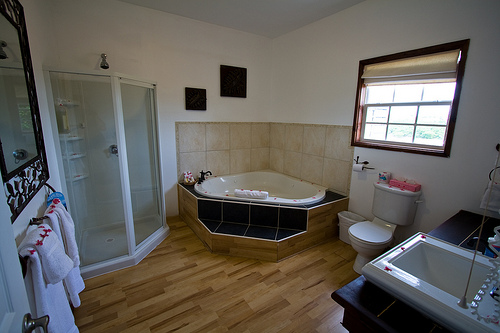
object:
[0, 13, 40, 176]
mirror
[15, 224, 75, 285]
towel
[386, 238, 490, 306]
white sink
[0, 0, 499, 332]
bathroom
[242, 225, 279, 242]
tile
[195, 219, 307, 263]
stairs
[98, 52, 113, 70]
shower head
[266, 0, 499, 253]
wall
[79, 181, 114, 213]
glass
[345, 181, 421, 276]
toilet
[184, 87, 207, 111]
pictures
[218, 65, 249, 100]
pictures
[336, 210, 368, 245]
waste bucket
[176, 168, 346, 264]
bathtub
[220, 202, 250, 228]
tile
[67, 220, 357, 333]
floor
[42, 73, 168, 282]
shower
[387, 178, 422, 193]
pink objects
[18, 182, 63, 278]
rack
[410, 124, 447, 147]
window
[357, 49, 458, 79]
blinds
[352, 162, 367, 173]
toilet paper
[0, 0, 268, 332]
wall